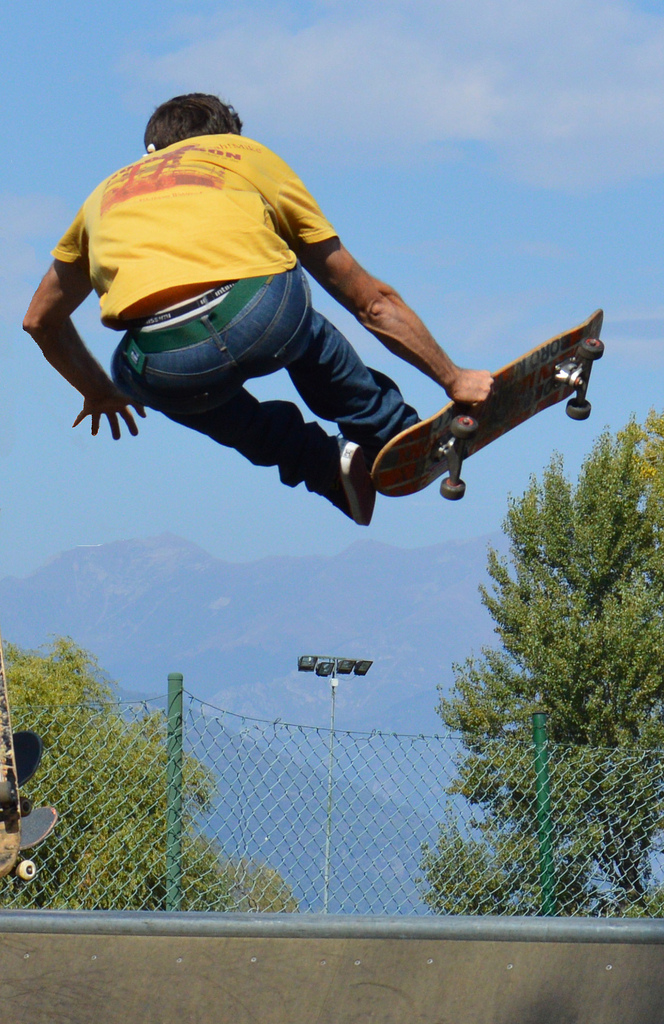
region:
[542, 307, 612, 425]
red and black wheels on skateboard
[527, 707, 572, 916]
green metal pole on fence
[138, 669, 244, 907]
green metal pole on chain link fence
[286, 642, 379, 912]
street light on pole behind fence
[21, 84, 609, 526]
man in yellow shirt on skateboard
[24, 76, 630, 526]
man in yellow shirt on skateboard in air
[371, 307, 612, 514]
logos on the bottom of skateboard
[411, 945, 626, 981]
metal screws in wood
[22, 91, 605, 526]
a man holding a skateboard with one hand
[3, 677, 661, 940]
a gray metal fence with green poles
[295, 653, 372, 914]
black floodlights on a metal pole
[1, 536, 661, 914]
high mountains covered in fog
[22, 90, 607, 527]
man performing a trick in the air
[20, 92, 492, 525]
man wearing a yellow shirt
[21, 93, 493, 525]
man wearing blue jeans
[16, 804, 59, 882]
skateboard with one yellow wheel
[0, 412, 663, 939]
a tall green tree behind a fence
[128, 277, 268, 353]
green underwear with a white and black band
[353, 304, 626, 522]
skateboard that the guy is riding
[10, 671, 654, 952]
fence around the skate park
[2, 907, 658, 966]
edge on the pipe for skater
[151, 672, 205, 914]
green post of the fence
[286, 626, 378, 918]
four light post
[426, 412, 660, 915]
tree on the right side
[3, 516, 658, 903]
mountains behind the skate park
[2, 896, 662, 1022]
half pipe in the skate park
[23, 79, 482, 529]
skateboarder in the air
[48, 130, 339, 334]
the shirt is short sleeved and yellow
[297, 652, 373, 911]
the lights on the pole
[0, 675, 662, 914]
the chain link fence is green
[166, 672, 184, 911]
the pole is green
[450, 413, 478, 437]
the wheel is black and red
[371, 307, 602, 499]
the wheels under the skateboard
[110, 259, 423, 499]
the jeans are blue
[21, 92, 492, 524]
the man is wearing shoes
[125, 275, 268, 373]
the belt is green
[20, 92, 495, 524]
the man is wearing a shirt and jeans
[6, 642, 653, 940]
gate that surrounds skate park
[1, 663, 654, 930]
gate that surrounds skate park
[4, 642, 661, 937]
gate that surrounds skate park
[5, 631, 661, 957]
gate that surrounds skate park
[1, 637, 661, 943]
gate that surrounds skate park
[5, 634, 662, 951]
gate that surrounds skate park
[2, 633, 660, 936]
gate that surrounds skate park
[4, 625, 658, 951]
gate that surrounds skate park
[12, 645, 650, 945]
gate that surrounds skate park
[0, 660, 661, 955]
gate that surrounds skate park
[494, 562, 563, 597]
green leaves on the tree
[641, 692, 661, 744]
green leaves on the tree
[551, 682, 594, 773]
green leaves on the tree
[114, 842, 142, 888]
green leaves on the tree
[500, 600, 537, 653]
green leaves on the tree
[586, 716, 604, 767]
green leaves on the tree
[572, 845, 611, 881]
green leaves on the tree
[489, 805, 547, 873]
green leaves on the tree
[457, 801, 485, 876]
green leaves on the tree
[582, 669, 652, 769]
green leaves on the tree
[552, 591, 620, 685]
green leaves on the tree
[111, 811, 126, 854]
green leaves on the tree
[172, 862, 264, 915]
green leaves on the tree